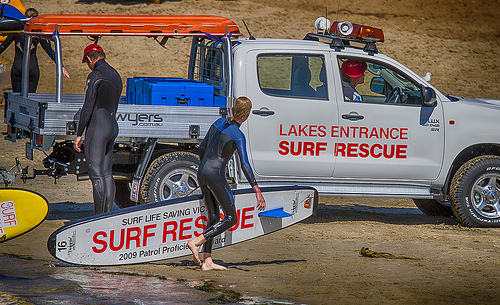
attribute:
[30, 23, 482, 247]
vehicle — rescue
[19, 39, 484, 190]
pickup — white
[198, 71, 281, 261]
person — wet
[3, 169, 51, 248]
surfboard — yellow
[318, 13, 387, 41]
light — top